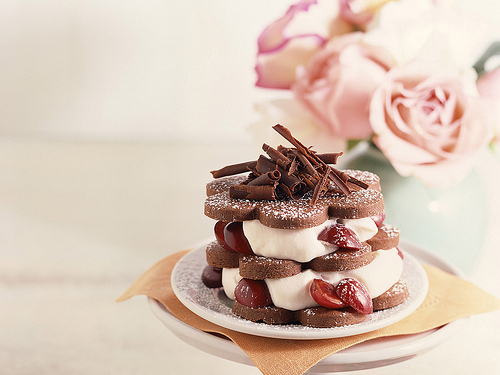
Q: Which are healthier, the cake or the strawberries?
A: The strawberries are healthier than the cake.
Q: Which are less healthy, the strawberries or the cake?
A: The cake are less healthy than the strawberries.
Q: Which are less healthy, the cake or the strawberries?
A: The cake are less healthy than the strawberries.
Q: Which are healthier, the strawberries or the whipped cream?
A: The strawberries are healthier than the whipped cream.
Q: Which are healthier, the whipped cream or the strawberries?
A: The strawberries are healthier than the whipped cream.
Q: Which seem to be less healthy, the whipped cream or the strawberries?
A: The whipped cream are less healthy than the strawberries.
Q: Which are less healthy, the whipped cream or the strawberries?
A: The whipped cream are less healthy than the strawberries.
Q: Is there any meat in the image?
A: No, there is no meat.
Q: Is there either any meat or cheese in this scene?
A: No, there are no meat or cheese.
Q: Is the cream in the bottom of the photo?
A: Yes, the cream is in the bottom of the image.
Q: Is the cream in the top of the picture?
A: No, the cream is in the bottom of the image.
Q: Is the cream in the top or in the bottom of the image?
A: The cream is in the bottom of the image.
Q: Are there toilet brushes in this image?
A: No, there are no toilet brushes.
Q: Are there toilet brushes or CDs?
A: No, there are no toilet brushes or cds.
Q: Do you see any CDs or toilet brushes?
A: No, there are no toilet brushes or cds.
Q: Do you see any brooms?
A: No, there are no brooms.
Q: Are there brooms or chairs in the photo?
A: No, there are no brooms or chairs.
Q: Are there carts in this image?
A: No, there are no carts.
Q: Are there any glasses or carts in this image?
A: No, there are no carts or glasses.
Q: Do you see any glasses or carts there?
A: No, there are no carts or glasses.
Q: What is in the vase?
A: The rose is in the vase.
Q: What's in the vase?
A: The rose is in the vase.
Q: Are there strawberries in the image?
A: Yes, there are strawberries.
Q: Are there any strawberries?
A: Yes, there are strawberries.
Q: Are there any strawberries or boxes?
A: Yes, there are strawberries.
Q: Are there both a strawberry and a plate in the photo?
A: Yes, there are both a strawberry and a plate.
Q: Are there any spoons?
A: No, there are no spoons.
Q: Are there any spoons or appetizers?
A: No, there are no spoons or appetizers.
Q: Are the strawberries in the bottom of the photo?
A: Yes, the strawberries are in the bottom of the image.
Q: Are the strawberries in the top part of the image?
A: No, the strawberries are in the bottom of the image.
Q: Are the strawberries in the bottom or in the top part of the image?
A: The strawberries are in the bottom of the image.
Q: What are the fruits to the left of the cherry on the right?
A: The fruits are strawberries.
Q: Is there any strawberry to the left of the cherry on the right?
A: Yes, there are strawberries to the left of the cherry.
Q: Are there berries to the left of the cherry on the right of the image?
A: No, there are strawberries to the left of the cherry.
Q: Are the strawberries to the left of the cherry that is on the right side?
A: Yes, the strawberries are to the left of the cherry.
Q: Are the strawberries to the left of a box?
A: No, the strawberries are to the left of the cherry.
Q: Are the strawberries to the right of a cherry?
A: Yes, the strawberries are to the right of a cherry.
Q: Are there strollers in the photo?
A: No, there are no strollers.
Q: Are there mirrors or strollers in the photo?
A: No, there are no strollers or mirrors.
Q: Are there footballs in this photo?
A: No, there are no footballs.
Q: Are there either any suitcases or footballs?
A: No, there are no footballs or suitcases.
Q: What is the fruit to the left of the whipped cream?
A: The fruit is a cherry.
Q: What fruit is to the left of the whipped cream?
A: The fruit is a cherry.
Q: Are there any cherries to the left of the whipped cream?
A: Yes, there is a cherry to the left of the whipped cream.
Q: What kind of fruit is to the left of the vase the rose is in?
A: The fruit is a cherry.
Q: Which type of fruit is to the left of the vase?
A: The fruit is a cherry.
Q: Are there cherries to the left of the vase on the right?
A: Yes, there is a cherry to the left of the vase.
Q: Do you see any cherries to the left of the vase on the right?
A: Yes, there is a cherry to the left of the vase.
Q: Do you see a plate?
A: Yes, there is a plate.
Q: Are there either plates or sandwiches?
A: Yes, there is a plate.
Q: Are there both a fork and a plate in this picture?
A: No, there is a plate but no forks.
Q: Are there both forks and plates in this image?
A: No, there is a plate but no forks.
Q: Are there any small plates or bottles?
A: Yes, there is a small plate.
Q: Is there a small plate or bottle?
A: Yes, there is a small plate.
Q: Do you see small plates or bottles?
A: Yes, there is a small plate.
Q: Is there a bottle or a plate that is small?
A: Yes, the plate is small.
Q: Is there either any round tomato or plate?
A: Yes, there is a round plate.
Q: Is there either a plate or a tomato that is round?
A: Yes, the plate is round.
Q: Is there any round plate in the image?
A: Yes, there is a round plate.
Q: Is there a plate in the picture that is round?
A: Yes, there is a plate that is round.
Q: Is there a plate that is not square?
A: Yes, there is a round plate.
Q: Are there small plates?
A: Yes, there is a small plate.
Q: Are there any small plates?
A: Yes, there is a small plate.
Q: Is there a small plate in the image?
A: Yes, there is a small plate.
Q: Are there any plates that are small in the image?
A: Yes, there is a small plate.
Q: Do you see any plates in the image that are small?
A: Yes, there is a plate that is small.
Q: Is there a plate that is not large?
A: Yes, there is a small plate.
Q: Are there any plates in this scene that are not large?
A: Yes, there is a small plate.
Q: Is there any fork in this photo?
A: No, there are no forks.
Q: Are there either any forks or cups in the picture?
A: No, there are no forks or cups.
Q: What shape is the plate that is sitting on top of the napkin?
A: The plate is round.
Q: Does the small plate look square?
A: No, the plate is round.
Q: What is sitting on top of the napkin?
A: The plate is sitting on top of the napkin.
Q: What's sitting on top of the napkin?
A: The plate is sitting on top of the napkin.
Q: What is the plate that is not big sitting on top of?
A: The plate is sitting on top of the napkin.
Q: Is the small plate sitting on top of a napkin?
A: Yes, the plate is sitting on top of a napkin.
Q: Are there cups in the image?
A: No, there are no cups.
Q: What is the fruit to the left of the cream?
A: The fruit is a cherry.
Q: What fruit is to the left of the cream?
A: The fruit is a cherry.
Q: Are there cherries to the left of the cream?
A: Yes, there is a cherry to the left of the cream.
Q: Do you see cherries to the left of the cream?
A: Yes, there is a cherry to the left of the cream.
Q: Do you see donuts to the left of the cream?
A: No, there is a cherry to the left of the cream.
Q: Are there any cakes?
A: Yes, there is a cake.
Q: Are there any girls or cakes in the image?
A: Yes, there is a cake.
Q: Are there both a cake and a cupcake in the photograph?
A: No, there is a cake but no cupcakes.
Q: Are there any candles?
A: No, there are no candles.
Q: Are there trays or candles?
A: No, there are no candles or trays.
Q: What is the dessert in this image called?
A: The dessert is a cake.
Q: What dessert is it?
A: The dessert is a cake.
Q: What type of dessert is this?
A: This is a cake.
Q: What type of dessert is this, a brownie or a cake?
A: This is a cake.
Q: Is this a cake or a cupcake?
A: This is a cake.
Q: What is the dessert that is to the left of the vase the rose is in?
A: The dessert is a cake.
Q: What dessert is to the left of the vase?
A: The dessert is a cake.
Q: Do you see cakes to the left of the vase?
A: Yes, there is a cake to the left of the vase.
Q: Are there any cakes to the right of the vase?
A: No, the cake is to the left of the vase.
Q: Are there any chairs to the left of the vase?
A: No, there is a cake to the left of the vase.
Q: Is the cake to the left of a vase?
A: Yes, the cake is to the left of a vase.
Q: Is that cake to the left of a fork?
A: No, the cake is to the left of a vase.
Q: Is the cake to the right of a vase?
A: No, the cake is to the left of a vase.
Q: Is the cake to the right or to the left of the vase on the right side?
A: The cake is to the left of the vase.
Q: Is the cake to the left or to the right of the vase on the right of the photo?
A: The cake is to the left of the vase.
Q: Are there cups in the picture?
A: No, there are no cups.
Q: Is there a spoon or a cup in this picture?
A: No, there are no cups or spoons.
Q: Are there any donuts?
A: No, there are no donuts.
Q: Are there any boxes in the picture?
A: No, there are no boxes.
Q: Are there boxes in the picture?
A: No, there are no boxes.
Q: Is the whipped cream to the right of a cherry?
A: Yes, the whipped cream is to the right of a cherry.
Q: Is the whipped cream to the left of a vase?
A: Yes, the whipped cream is to the left of a vase.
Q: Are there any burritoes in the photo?
A: No, there are no burritoes.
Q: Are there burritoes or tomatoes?
A: No, there are no burritoes or tomatoes.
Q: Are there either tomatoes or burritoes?
A: No, there are no burritoes or tomatoes.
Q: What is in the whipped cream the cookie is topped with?
A: The cherry is in the whipped cream.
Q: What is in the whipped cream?
A: The cherry is in the whipped cream.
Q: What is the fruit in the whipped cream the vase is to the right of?
A: The fruit is a cherry.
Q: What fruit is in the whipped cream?
A: The fruit is a cherry.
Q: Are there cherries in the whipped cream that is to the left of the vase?
A: Yes, there is a cherry in the whipped cream.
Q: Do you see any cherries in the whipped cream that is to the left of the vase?
A: Yes, there is a cherry in the whipped cream.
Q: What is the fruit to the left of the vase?
A: The fruit is a cherry.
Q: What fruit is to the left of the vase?
A: The fruit is a cherry.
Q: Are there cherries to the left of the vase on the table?
A: Yes, there is a cherry to the left of the vase.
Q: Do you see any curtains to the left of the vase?
A: No, there is a cherry to the left of the vase.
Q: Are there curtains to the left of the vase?
A: No, there is a cherry to the left of the vase.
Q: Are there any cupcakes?
A: No, there are no cupcakes.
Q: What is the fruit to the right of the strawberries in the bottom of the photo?
A: The fruit is a cherry.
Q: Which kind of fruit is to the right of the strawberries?
A: The fruit is a cherry.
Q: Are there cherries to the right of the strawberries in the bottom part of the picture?
A: Yes, there is a cherry to the right of the strawberries.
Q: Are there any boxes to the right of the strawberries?
A: No, there is a cherry to the right of the strawberries.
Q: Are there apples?
A: No, there are no apples.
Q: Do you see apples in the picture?
A: No, there are no apples.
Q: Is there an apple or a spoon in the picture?
A: No, there are no apples or spoons.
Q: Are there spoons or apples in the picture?
A: No, there are no apples or spoons.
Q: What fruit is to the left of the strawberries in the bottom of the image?
A: The fruit is a cherry.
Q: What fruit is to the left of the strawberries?
A: The fruit is a cherry.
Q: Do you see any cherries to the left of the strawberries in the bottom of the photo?
A: Yes, there is a cherry to the left of the strawberries.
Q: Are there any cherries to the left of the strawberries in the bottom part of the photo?
A: Yes, there is a cherry to the left of the strawberries.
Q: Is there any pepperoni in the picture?
A: No, there is no pepperoni.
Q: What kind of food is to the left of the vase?
A: The food is chocolate.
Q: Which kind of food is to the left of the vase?
A: The food is chocolate.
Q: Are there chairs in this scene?
A: No, there are no chairs.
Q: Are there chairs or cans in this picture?
A: No, there are no chairs or cans.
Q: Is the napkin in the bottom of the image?
A: Yes, the napkin is in the bottom of the image.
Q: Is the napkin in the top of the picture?
A: No, the napkin is in the bottom of the image.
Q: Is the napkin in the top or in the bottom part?
A: The napkin is in the bottom of the image.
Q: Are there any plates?
A: Yes, there is a plate.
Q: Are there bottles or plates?
A: Yes, there is a plate.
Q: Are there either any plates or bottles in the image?
A: Yes, there is a plate.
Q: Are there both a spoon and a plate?
A: No, there is a plate but no spoons.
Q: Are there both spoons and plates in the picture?
A: No, there is a plate but no spoons.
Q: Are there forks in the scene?
A: No, there are no forks.